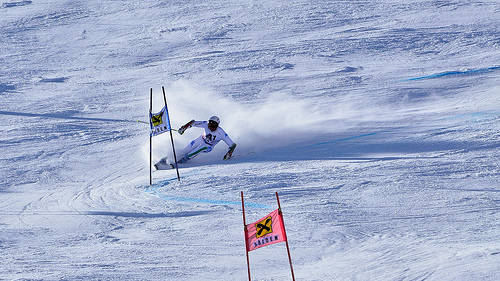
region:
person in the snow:
[166, 84, 258, 179]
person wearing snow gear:
[141, 87, 276, 192]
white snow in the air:
[246, 73, 299, 133]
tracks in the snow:
[263, 125, 400, 217]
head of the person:
[201, 105, 228, 139]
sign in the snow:
[226, 178, 303, 269]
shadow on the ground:
[59, 90, 120, 138]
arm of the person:
[221, 125, 248, 176]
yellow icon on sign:
[251, 210, 277, 242]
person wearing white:
[176, 95, 246, 177]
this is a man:
[176, 110, 238, 170]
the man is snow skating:
[178, 103, 235, 175]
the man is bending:
[178, 113, 233, 171]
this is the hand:
[213, 137, 240, 159]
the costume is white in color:
[190, 128, 217, 151]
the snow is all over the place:
[363, 145, 462, 280]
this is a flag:
[240, 201, 283, 273]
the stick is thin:
[270, 188, 282, 203]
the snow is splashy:
[246, 92, 294, 124]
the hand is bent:
[224, 137, 234, 159]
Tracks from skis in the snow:
[46, 173, 128, 210]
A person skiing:
[153, 109, 239, 175]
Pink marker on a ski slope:
[226, 174, 302, 279]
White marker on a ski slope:
[137, 81, 190, 188]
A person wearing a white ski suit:
[153, 107, 250, 171]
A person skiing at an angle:
[152, 104, 247, 173]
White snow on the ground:
[296, 255, 351, 278]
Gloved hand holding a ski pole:
[173, 122, 188, 138]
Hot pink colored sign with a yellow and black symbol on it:
[244, 209, 289, 251]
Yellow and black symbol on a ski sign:
[252, 214, 277, 239]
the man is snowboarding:
[122, 88, 243, 180]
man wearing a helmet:
[197, 108, 221, 136]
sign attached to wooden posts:
[125, 88, 177, 135]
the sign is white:
[143, 103, 178, 139]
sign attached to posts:
[235, 211, 297, 248]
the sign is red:
[235, 212, 302, 250]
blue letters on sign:
[229, 228, 284, 246]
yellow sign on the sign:
[240, 215, 275, 240]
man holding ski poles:
[133, 111, 254, 163]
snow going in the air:
[135, 73, 352, 155]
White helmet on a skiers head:
[209, 115, 218, 123]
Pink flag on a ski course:
[240, 210, 292, 250]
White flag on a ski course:
[143, 108, 173, 132]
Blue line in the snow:
[144, 184, 272, 210]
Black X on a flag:
[254, 219, 273, 233]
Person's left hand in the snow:
[223, 135, 239, 167]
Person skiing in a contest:
[131, 96, 242, 178]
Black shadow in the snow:
[8, 202, 222, 223]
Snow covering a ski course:
[1, 3, 496, 280]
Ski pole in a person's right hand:
[136, 115, 183, 134]